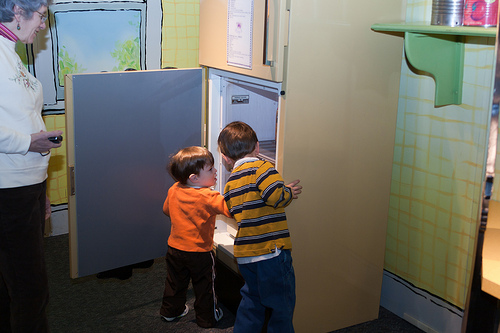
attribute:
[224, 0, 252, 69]
paper — white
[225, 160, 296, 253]
shirt — striped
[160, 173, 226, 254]
shirt — orange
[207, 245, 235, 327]
stripe — white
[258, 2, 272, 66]
handle — brown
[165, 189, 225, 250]
shirt — orange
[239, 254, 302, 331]
jeans — blue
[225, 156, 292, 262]
shirt — yellow , black, striped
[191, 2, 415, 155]
refrigerator — tan, open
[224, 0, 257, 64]
paper — white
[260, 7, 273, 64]
handle — silver, metal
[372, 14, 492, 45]
shelf — wooden, green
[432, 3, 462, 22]
canister — silver, metal